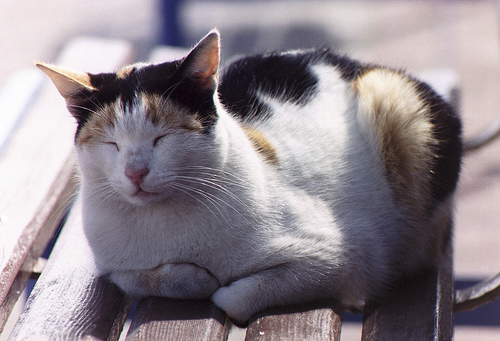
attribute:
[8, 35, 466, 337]
bench — brown, wooden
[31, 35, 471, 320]
cat — white, calico, sleeping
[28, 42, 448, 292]
cat's whiskers — spotted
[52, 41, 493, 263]
cat — calico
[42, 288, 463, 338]
bench — wooden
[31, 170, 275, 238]
whiskers — white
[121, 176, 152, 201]
mouth — closed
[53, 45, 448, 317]
cat — brown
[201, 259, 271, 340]
paw — white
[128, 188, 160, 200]
mouth — closed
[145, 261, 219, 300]
paw — white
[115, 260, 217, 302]
paw — white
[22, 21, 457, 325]
cat — calico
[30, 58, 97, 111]
ear — brown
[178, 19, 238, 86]
ear — brown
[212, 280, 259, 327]
paw — white